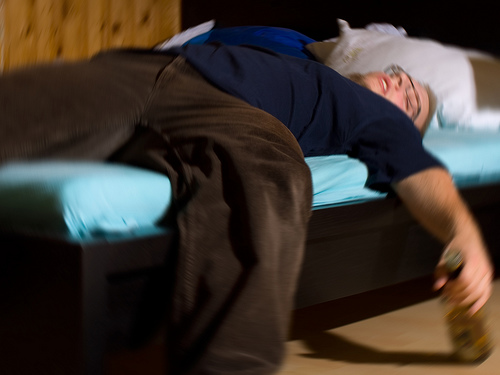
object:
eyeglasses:
[383, 63, 423, 124]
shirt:
[178, 41, 449, 187]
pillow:
[307, 35, 500, 129]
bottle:
[439, 251, 497, 368]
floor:
[275, 278, 500, 375]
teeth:
[381, 79, 387, 91]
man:
[0, 29, 496, 375]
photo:
[0, 0, 499, 375]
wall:
[0, 0, 182, 73]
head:
[349, 69, 438, 139]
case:
[324, 17, 500, 130]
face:
[363, 70, 431, 130]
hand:
[433, 231, 493, 320]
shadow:
[297, 329, 463, 368]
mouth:
[379, 75, 392, 96]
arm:
[362, 120, 478, 237]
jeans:
[0, 46, 314, 374]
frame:
[0, 183, 500, 373]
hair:
[420, 81, 440, 138]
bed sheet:
[1, 81, 500, 246]